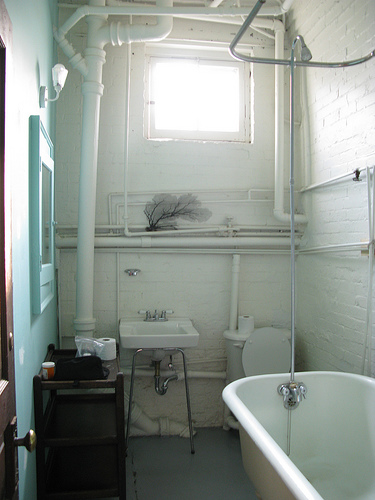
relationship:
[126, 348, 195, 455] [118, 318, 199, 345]
legs under sink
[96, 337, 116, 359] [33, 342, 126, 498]
toilet paper on wood stand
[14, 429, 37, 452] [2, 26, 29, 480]
knob on door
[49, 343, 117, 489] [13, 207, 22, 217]
shelf against wall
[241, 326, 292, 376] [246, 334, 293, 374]
lid with lid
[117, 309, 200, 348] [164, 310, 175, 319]
sink has knobs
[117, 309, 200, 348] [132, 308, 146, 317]
sink has left knob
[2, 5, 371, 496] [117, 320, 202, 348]
bathroom has sink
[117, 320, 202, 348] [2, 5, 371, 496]
sink in bathroom